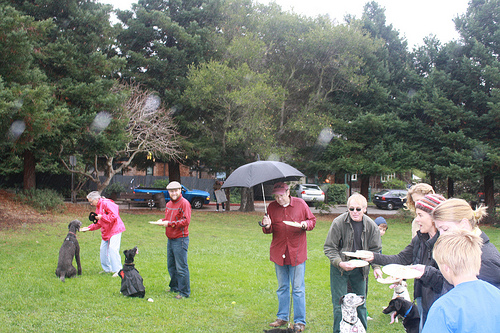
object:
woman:
[76, 190, 127, 276]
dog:
[339, 292, 368, 332]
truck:
[127, 184, 213, 210]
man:
[262, 184, 317, 332]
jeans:
[274, 258, 308, 326]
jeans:
[166, 235, 187, 297]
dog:
[56, 220, 81, 284]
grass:
[0, 210, 500, 333]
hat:
[415, 193, 444, 212]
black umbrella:
[221, 159, 306, 227]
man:
[157, 181, 192, 300]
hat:
[165, 180, 181, 190]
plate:
[147, 221, 163, 225]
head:
[414, 194, 444, 234]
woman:
[400, 197, 499, 330]